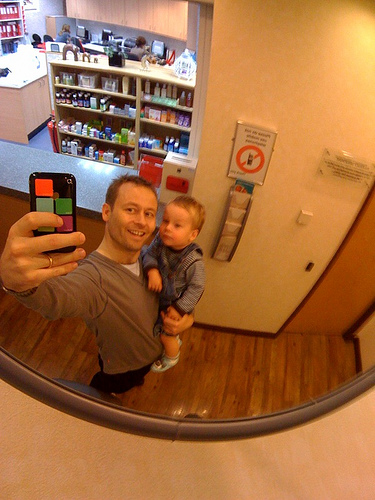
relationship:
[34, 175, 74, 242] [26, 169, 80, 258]
blocks are on back of phone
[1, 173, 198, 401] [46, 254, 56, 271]
man wearing a ring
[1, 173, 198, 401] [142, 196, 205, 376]
man holding boy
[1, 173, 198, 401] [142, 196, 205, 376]
man with a boy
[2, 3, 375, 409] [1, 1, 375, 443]
reflection in mirror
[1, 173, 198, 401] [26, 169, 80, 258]
man holding phone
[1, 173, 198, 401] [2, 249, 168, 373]
man wearing a shirt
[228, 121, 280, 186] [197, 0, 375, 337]
sign on wall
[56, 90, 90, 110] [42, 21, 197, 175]
bottles are on shelf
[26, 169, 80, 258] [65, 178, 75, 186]
phone has a camera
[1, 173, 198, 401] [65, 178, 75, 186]
man holding camera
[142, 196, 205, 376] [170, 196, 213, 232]
boy has hair